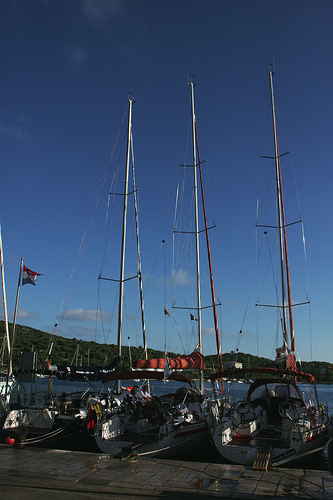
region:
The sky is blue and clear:
[26, 109, 127, 193]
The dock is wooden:
[55, 441, 156, 498]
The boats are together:
[11, 352, 330, 461]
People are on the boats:
[115, 374, 200, 419]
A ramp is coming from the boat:
[238, 434, 292, 485]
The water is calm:
[140, 367, 191, 404]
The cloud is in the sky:
[155, 242, 219, 310]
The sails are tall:
[40, 109, 332, 373]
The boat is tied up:
[3, 419, 82, 468]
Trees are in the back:
[218, 330, 290, 394]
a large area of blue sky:
[0, 0, 332, 364]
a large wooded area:
[0, 319, 332, 381]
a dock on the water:
[0, 445, 332, 499]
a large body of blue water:
[0, 376, 332, 469]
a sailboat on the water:
[209, 55, 331, 466]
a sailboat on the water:
[94, 69, 236, 458]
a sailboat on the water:
[0, 89, 155, 447]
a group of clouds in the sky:
[124, 268, 206, 288]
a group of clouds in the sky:
[182, 326, 254, 339]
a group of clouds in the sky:
[54, 307, 139, 323]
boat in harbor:
[34, 374, 204, 442]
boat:
[180, 373, 321, 479]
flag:
[11, 252, 43, 289]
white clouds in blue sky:
[13, 20, 39, 55]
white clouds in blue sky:
[1, 79, 47, 137]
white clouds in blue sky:
[14, 160, 71, 220]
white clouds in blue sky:
[73, 38, 108, 70]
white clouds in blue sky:
[215, 58, 235, 86]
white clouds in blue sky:
[245, 183, 261, 225]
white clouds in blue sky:
[222, 206, 248, 244]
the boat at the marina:
[210, 90, 326, 482]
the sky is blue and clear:
[4, 2, 331, 186]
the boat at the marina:
[84, 378, 232, 466]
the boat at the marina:
[0, 376, 148, 452]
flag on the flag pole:
[3, 254, 59, 369]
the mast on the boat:
[255, 65, 310, 391]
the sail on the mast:
[211, 355, 307, 395]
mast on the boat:
[176, 79, 227, 401]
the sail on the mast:
[128, 348, 203, 374]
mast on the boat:
[113, 122, 145, 399]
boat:
[39, 359, 168, 451]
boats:
[96, 381, 272, 458]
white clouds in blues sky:
[24, 117, 59, 150]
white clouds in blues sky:
[7, 26, 46, 69]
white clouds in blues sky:
[63, 209, 83, 237]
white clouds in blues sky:
[150, 226, 177, 262]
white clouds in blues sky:
[135, 141, 183, 162]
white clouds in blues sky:
[141, 260, 180, 319]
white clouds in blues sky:
[211, 176, 242, 204]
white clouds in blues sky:
[302, 203, 331, 263]